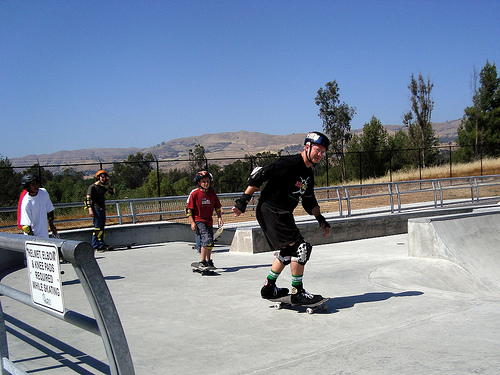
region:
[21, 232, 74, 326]
A sign with skate park rules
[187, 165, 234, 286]
a boy in a red shirt skate boarding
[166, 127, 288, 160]
mountains behind the park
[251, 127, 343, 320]
an adult man skate boarding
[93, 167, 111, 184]
an orange helmet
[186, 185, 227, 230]
a red shirt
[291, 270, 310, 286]
green striped socks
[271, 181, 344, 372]
rails in the park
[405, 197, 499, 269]
a ramp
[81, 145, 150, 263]
kid in the background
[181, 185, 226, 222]
young male skateboarders wearing red shirt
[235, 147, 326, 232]
male skateboarders wearing black shirt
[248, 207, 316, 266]
male skateboarders wearing black and white shorts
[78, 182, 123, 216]
boy wearing black shirt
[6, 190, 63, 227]
man wearing white shirt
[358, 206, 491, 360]
gray pavement in skate park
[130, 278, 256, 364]
gray pavement in skate park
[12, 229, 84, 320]
black and white sign on gray fence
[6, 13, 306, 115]
blue sky without clouds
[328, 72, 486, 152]
green trees near skate park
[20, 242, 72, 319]
Sign on a gate.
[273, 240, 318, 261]
Man is wearing knee pads.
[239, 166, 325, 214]
Man is wearing elbow pads.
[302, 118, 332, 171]
Man is wearing a helmet.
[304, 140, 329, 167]
The man is wearing glasses.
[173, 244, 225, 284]
Kid is on a skateboard.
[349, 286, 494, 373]
The ground is cement.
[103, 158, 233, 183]
Fence posts are black.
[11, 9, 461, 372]
Picture was taken at a skate park.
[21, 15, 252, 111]
Mountains in the background.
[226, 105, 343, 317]
Adult man riding a skateboard.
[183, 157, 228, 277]
Red shirted child skateboarding.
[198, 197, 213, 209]
American flag on T-shirt.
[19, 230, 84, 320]
Sign about skateboarding.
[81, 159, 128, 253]
Skateboarder onlooker.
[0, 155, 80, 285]
White shirt skateboarding onlooker.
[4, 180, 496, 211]
Metal guardrails.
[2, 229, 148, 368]
Metal guardrails with sign.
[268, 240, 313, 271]
Black and white kneepads.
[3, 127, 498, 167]
Brown, arid hills in the background near skyline.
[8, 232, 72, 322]
A SIGN ON THE RAIL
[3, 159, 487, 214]
BLACK CHAIN LINK FENCE IN THE BACK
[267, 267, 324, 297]
HE'S WEARING GREEN SOCKS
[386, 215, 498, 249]
A RAMP FOR TRICKS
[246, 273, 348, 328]
NO FEET ON THE GROUND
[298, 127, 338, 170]
HELMET ON THE HEAD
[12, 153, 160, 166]
BARBED WIRE ON TOP OF THE FENCE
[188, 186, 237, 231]
THE BOY HAS A RED SHIRT ON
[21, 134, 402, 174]
HILLS IN THE DISTANCE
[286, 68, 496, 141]
TALL TREES OUTSIDE THE FENCE